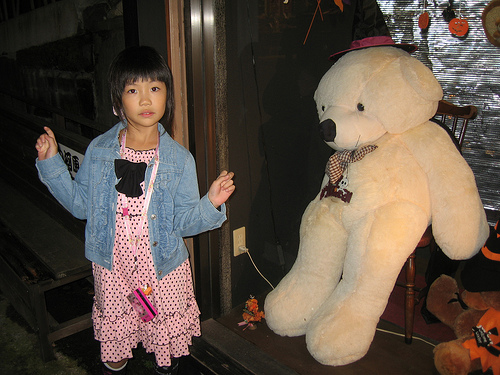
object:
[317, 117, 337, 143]
nose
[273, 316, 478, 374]
floor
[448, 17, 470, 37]
jack-o-lantern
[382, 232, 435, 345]
chair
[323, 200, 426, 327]
leg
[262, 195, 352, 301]
leg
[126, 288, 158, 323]
purse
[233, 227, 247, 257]
desert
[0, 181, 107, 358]
bench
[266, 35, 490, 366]
bear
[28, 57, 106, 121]
chair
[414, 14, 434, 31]
pumpkin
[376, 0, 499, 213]
window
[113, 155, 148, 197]
bow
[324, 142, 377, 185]
bow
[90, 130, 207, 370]
dress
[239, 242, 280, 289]
cable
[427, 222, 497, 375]
teddy bear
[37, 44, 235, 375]
girl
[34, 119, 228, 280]
denim jacket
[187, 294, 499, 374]
shelf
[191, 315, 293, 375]
bench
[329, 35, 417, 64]
hat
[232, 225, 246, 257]
outlet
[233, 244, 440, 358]
cord